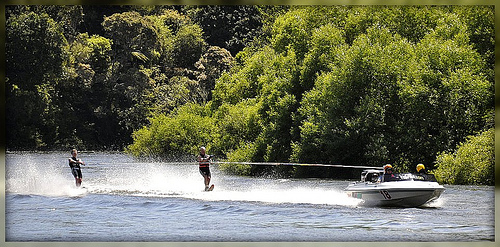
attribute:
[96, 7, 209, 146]
tree — green , group 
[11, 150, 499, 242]
water —  river 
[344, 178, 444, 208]
boat — small, white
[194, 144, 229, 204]
skiier — on right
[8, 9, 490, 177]
plants — green 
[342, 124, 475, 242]
boat — white, small